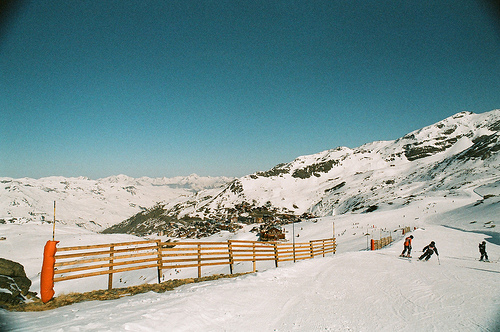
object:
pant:
[402, 245, 413, 255]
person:
[478, 240, 490, 262]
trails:
[286, 178, 498, 251]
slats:
[53, 263, 162, 283]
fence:
[52, 237, 337, 283]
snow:
[0, 110, 500, 332]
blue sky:
[0, 0, 500, 179]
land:
[0, 110, 500, 332]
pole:
[53, 200, 57, 241]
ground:
[0, 107, 500, 332]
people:
[401, 234, 415, 257]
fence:
[404, 226, 411, 235]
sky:
[0, 0, 500, 181]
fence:
[374, 236, 393, 251]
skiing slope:
[0, 223, 500, 332]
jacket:
[403, 237, 411, 247]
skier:
[389, 224, 419, 262]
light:
[0, 76, 258, 175]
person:
[418, 240, 440, 262]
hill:
[0, 108, 500, 332]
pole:
[333, 221, 336, 238]